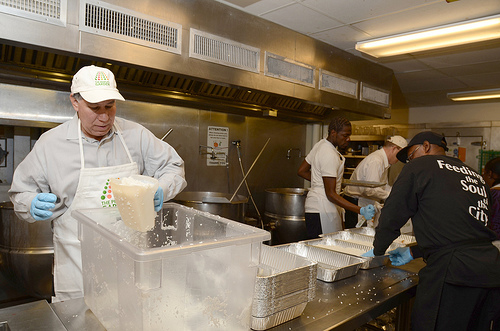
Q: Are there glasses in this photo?
A: No, there are no glasses.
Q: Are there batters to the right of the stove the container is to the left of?
A: Yes, there is a batter to the right of the stove.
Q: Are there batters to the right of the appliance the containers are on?
A: Yes, there is a batter to the right of the stove.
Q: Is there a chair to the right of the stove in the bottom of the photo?
A: No, there is a batter to the right of the stove.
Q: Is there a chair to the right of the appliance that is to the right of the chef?
A: No, there is a batter to the right of the stove.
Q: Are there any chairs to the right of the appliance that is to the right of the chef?
A: No, there is a batter to the right of the stove.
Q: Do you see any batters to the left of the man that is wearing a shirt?
A: Yes, there is a batter to the left of the man.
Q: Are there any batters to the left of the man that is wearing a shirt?
A: Yes, there is a batter to the left of the man.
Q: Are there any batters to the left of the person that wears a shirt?
A: Yes, there is a batter to the left of the man.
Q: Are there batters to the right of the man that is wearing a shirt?
A: No, the batter is to the left of the man.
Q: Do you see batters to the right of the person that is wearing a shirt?
A: No, the batter is to the left of the man.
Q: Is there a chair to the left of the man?
A: No, there is a batter to the left of the man.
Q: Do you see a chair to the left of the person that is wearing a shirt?
A: No, there is a batter to the left of the man.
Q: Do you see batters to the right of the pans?
A: Yes, there is a batter to the right of the pans.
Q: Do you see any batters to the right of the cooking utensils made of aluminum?
A: Yes, there is a batter to the right of the pans.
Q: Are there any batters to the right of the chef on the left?
A: Yes, there is a batter to the right of the chef.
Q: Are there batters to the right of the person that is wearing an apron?
A: Yes, there is a batter to the right of the chef.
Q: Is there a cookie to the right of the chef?
A: No, there is a batter to the right of the chef.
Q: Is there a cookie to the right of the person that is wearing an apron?
A: No, there is a batter to the right of the chef.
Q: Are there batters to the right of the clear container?
A: Yes, there is a batter to the right of the container.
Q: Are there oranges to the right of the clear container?
A: No, there is a batter to the right of the container.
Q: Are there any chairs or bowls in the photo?
A: No, there are no bowls or chairs.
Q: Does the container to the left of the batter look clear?
A: Yes, the container is clear.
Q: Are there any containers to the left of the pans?
A: Yes, there is a container to the left of the pans.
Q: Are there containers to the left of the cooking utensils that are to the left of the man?
A: Yes, there is a container to the left of the pans.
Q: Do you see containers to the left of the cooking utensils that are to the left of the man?
A: Yes, there is a container to the left of the pans.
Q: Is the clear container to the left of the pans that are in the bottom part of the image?
A: Yes, the container is to the left of the pans.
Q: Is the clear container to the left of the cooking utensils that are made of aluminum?
A: Yes, the container is to the left of the pans.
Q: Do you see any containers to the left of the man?
A: Yes, there is a container to the left of the man.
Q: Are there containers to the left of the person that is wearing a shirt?
A: Yes, there is a container to the left of the man.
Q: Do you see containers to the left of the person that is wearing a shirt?
A: Yes, there is a container to the left of the man.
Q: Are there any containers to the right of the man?
A: No, the container is to the left of the man.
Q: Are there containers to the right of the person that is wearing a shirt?
A: No, the container is to the left of the man.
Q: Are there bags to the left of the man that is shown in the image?
A: No, there is a container to the left of the man.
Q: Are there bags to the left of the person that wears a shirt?
A: No, there is a container to the left of the man.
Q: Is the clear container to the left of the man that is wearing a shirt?
A: Yes, the container is to the left of the man.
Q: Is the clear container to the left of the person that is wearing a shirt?
A: Yes, the container is to the left of the man.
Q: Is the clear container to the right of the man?
A: No, the container is to the left of the man.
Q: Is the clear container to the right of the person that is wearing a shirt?
A: No, the container is to the left of the man.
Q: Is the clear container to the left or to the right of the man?
A: The container is to the left of the man.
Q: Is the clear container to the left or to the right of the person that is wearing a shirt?
A: The container is to the left of the man.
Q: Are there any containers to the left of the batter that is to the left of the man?
A: Yes, there is a container to the left of the batter.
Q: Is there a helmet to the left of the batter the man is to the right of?
A: No, there is a container to the left of the batter.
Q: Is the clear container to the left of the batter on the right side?
A: Yes, the container is to the left of the batter.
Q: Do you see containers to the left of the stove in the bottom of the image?
A: Yes, there is a container to the left of the stove.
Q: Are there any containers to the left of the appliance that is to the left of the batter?
A: Yes, there is a container to the left of the stove.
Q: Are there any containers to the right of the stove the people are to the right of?
A: No, the container is to the left of the stove.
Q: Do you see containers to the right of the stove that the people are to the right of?
A: No, the container is to the left of the stove.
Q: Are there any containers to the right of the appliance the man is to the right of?
A: No, the container is to the left of the stove.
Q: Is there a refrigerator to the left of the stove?
A: No, there is a container to the left of the stove.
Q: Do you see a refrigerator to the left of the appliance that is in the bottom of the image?
A: No, there is a container to the left of the stove.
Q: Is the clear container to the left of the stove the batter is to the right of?
A: Yes, the container is to the left of the stove.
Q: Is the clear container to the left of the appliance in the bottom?
A: Yes, the container is to the left of the stove.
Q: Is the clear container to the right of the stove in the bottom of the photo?
A: No, the container is to the left of the stove.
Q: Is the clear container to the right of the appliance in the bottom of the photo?
A: No, the container is to the left of the stove.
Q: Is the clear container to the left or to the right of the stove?
A: The container is to the left of the stove.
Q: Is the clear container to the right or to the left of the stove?
A: The container is to the left of the stove.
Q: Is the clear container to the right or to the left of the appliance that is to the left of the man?
A: The container is to the left of the stove.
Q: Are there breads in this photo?
A: No, there are no breads.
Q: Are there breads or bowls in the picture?
A: No, there are no breads or bowls.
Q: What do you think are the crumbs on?
A: The crumbs are on the counter.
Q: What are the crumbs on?
A: The crumbs are on the counter.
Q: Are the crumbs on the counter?
A: Yes, the crumbs are on the counter.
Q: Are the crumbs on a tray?
A: No, the crumbs are on the counter.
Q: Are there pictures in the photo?
A: No, there are no pictures.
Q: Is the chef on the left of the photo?
A: Yes, the chef is on the left of the image.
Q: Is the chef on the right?
A: No, the chef is on the left of the image.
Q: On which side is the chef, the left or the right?
A: The chef is on the left of the image.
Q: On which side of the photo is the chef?
A: The chef is on the left of the image.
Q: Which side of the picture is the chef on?
A: The chef is on the left of the image.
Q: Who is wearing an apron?
A: The chef is wearing an apron.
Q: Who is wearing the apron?
A: The chef is wearing an apron.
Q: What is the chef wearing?
A: The chef is wearing an apron.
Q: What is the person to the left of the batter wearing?
A: The chef is wearing an apron.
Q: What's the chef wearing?
A: The chef is wearing an apron.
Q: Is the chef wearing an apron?
A: Yes, the chef is wearing an apron.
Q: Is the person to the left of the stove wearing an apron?
A: Yes, the chef is wearing an apron.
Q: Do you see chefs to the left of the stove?
A: Yes, there is a chef to the left of the stove.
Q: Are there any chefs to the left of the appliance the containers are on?
A: Yes, there is a chef to the left of the stove.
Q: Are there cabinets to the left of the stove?
A: No, there is a chef to the left of the stove.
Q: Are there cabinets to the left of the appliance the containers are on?
A: No, there is a chef to the left of the stove.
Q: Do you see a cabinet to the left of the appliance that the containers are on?
A: No, there is a chef to the left of the stove.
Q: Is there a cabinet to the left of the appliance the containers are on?
A: No, there is a chef to the left of the stove.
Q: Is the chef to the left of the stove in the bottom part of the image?
A: Yes, the chef is to the left of the stove.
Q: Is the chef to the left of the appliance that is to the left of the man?
A: Yes, the chef is to the left of the stove.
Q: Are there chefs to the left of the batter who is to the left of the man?
A: Yes, there is a chef to the left of the batter.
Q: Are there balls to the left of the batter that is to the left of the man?
A: No, there is a chef to the left of the batter.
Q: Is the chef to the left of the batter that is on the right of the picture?
A: Yes, the chef is to the left of the batter.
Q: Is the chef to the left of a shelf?
A: No, the chef is to the left of the batter.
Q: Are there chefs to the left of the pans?
A: Yes, there is a chef to the left of the pans.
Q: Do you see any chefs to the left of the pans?
A: Yes, there is a chef to the left of the pans.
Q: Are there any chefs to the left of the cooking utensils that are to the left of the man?
A: Yes, there is a chef to the left of the pans.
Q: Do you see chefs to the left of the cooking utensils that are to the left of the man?
A: Yes, there is a chef to the left of the pans.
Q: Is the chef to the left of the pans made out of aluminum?
A: Yes, the chef is to the left of the pans.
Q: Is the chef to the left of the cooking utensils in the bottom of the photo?
A: Yes, the chef is to the left of the pans.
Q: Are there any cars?
A: No, there are no cars.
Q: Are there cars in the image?
A: No, there are no cars.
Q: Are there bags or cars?
A: No, there are no cars or bags.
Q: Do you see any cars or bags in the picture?
A: No, there are no cars or bags.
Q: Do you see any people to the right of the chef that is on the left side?
A: Yes, there are people to the right of the chef.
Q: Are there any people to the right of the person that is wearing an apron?
A: Yes, there are people to the right of the chef.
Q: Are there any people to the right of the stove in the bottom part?
A: Yes, there are people to the right of the stove.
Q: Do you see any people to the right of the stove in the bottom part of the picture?
A: Yes, there are people to the right of the stove.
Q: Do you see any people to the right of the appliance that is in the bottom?
A: Yes, there are people to the right of the stove.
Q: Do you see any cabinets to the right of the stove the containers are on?
A: No, there are people to the right of the stove.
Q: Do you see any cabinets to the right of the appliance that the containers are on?
A: No, there are people to the right of the stove.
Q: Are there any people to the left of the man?
A: Yes, there are people to the left of the man.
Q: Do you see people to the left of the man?
A: Yes, there are people to the left of the man.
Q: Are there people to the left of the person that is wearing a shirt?
A: Yes, there are people to the left of the man.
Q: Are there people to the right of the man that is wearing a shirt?
A: No, the people are to the left of the man.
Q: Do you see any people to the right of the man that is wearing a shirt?
A: No, the people are to the left of the man.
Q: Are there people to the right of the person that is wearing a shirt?
A: No, the people are to the left of the man.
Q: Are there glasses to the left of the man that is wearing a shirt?
A: No, there are people to the left of the man.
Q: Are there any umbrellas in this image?
A: No, there are no umbrellas.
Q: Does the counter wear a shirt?
A: Yes, the counter wears a shirt.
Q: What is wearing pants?
A: The counter is wearing pants.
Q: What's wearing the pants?
A: The counter is wearing pants.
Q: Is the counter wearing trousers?
A: Yes, the counter is wearing trousers.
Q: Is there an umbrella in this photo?
A: No, there are no umbrellas.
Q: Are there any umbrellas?
A: No, there are no umbrellas.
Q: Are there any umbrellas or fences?
A: No, there are no umbrellas or fences.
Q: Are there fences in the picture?
A: No, there are no fences.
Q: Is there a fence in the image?
A: No, there are no fences.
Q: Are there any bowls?
A: No, there are no bowls.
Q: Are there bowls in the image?
A: No, there are no bowls.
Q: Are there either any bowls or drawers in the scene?
A: No, there are no bowls or drawers.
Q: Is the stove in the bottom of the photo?
A: Yes, the stove is in the bottom of the image.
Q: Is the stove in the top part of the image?
A: No, the stove is in the bottom of the image.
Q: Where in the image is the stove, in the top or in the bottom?
A: The stove is in the bottom of the image.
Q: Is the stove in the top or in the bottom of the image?
A: The stove is in the bottom of the image.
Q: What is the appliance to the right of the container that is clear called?
A: The appliance is a stove.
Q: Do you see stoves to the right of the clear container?
A: Yes, there is a stove to the right of the container.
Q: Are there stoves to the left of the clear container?
A: No, the stove is to the right of the container.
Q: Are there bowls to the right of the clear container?
A: No, there is a stove to the right of the container.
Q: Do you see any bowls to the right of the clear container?
A: No, there is a stove to the right of the container.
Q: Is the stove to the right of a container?
A: Yes, the stove is to the right of a container.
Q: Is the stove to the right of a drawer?
A: No, the stove is to the right of a container.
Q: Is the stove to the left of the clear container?
A: No, the stove is to the right of the container.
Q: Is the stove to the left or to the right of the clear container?
A: The stove is to the right of the container.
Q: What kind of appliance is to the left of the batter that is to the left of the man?
A: The appliance is a stove.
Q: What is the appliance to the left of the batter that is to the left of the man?
A: The appliance is a stove.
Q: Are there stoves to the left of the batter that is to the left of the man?
A: Yes, there is a stove to the left of the batter.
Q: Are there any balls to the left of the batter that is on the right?
A: No, there is a stove to the left of the batter.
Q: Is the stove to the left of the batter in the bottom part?
A: Yes, the stove is to the left of the batter.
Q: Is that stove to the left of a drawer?
A: No, the stove is to the left of the batter.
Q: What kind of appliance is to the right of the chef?
A: The appliance is a stove.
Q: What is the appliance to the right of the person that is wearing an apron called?
A: The appliance is a stove.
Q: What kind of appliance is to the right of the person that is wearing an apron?
A: The appliance is a stove.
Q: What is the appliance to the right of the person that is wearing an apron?
A: The appliance is a stove.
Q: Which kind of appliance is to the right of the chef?
A: The appliance is a stove.